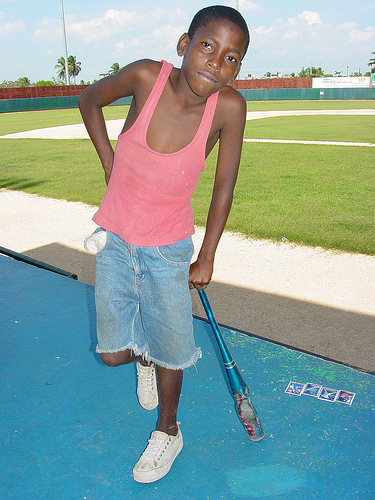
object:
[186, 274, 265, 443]
bat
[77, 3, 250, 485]
boy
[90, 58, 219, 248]
top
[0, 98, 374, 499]
floor